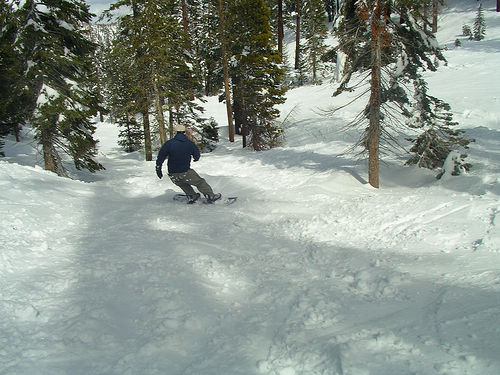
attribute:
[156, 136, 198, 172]
jacket — blue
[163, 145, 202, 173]
jacket — blue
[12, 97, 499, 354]
ground — snow-covered, white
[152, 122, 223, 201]
person — snowboarding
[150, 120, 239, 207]
person — snowboarding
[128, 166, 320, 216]
snowboard — pictured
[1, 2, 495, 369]
snow — covering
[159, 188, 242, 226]
snowboard — white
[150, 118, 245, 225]
man — snowboarding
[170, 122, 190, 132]
hat — white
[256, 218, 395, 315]
footprints — pictured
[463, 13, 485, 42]
pine tree — small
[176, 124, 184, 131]
hat — white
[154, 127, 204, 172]
hoodie — blue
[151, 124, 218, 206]
man — pictured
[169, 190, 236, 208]
snowboard — black, white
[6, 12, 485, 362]
ground — snow-covered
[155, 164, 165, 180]
glove — black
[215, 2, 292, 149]
pine tree — pictured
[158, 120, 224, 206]
snowboarder — pictured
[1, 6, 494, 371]
hill — snowy